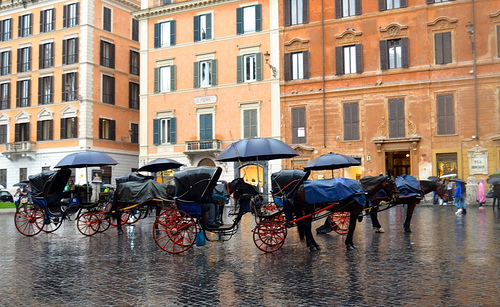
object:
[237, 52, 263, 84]
shutters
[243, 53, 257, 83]
window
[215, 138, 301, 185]
umbrella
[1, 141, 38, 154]
balcony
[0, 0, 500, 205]
building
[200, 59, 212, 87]
window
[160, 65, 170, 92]
window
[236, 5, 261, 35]
window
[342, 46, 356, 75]
window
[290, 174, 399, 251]
horse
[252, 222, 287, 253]
wheel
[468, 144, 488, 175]
plaque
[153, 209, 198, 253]
wheels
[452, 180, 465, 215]
person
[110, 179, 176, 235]
horse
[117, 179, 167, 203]
raincoat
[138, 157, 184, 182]
umbrella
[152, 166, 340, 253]
carriage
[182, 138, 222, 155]
balcony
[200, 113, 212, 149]
door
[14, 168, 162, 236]
carriage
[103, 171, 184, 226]
carriage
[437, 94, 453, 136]
window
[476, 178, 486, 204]
raincoat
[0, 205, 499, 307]
road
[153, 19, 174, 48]
window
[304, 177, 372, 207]
covering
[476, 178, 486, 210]
person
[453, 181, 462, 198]
blue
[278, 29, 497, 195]
wall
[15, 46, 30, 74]
window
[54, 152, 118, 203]
umbrella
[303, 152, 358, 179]
umbrella